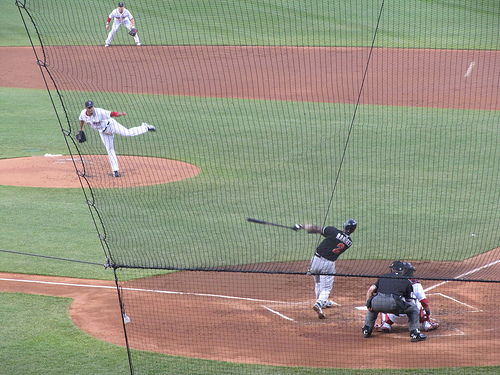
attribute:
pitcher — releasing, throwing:
[76, 101, 157, 179]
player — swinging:
[297, 220, 360, 319]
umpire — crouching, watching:
[361, 261, 428, 341]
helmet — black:
[342, 220, 356, 232]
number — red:
[332, 241, 346, 256]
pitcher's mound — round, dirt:
[2, 153, 198, 189]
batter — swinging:
[291, 218, 357, 318]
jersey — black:
[315, 225, 353, 264]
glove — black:
[76, 130, 87, 144]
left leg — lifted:
[113, 123, 157, 139]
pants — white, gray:
[308, 252, 336, 308]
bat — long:
[246, 217, 298, 231]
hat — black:
[389, 259, 405, 272]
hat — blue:
[85, 100, 93, 109]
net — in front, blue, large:
[16, 3, 499, 374]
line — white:
[422, 257, 499, 293]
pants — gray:
[366, 292, 423, 333]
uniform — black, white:
[309, 226, 355, 306]